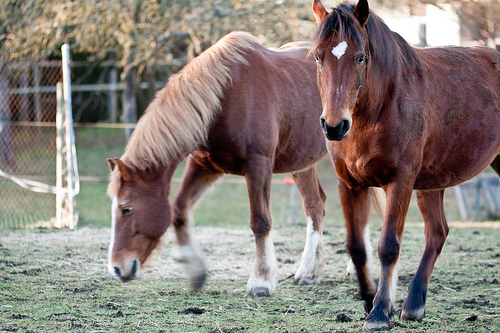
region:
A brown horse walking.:
[307, 0, 497, 327]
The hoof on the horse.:
[364, 321, 387, 329]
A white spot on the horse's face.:
[331, 40, 348, 58]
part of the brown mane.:
[376, 17, 393, 63]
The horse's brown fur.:
[436, 83, 486, 131]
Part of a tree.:
[125, 13, 204, 36]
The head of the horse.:
[108, 157, 171, 283]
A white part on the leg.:
[298, 218, 318, 280]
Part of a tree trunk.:
[118, 74, 140, 136]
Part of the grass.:
[73, 298, 150, 327]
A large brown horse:
[311, 0, 498, 331]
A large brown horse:
[106, 28, 389, 299]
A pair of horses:
[105, 0, 499, 331]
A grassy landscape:
[1, 130, 498, 331]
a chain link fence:
[0, 47, 77, 227]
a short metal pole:
[51, 80, 68, 223]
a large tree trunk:
[0, 69, 20, 166]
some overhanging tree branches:
[0, 0, 497, 127]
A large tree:
[0, 0, 311, 138]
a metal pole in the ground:
[289, 179, 299, 222]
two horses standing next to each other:
[90, 18, 495, 308]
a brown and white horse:
[85, 23, 326, 293]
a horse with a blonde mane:
[132, 33, 254, 160]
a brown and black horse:
[310, 9, 488, 296]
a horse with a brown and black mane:
[338, 4, 417, 72]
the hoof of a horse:
[363, 306, 388, 328]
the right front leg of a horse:
[172, 170, 208, 270]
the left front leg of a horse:
[245, 183, 283, 266]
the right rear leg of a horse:
[291, 174, 330, 264]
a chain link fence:
[18, 95, 48, 157]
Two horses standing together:
[62, 28, 489, 315]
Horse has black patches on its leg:
[349, 221, 418, 301]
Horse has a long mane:
[112, 65, 254, 176]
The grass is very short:
[214, 294, 219, 311]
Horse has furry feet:
[243, 222, 284, 300]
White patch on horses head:
[327, 25, 347, 71]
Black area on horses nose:
[319, 109, 359, 138]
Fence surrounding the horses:
[0, 38, 80, 273]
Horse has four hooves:
[177, 228, 340, 315]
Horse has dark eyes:
[350, 42, 370, 72]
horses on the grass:
[47, 15, 487, 322]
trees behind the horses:
[6, 2, 281, 54]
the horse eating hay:
[63, 147, 240, 293]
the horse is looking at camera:
[275, 8, 498, 318]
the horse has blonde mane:
[120, 42, 248, 149]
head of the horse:
[81, 150, 184, 282]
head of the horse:
[290, 0, 412, 160]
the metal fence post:
[24, 32, 96, 239]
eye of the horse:
[110, 199, 141, 217]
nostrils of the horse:
[305, 104, 363, 152]